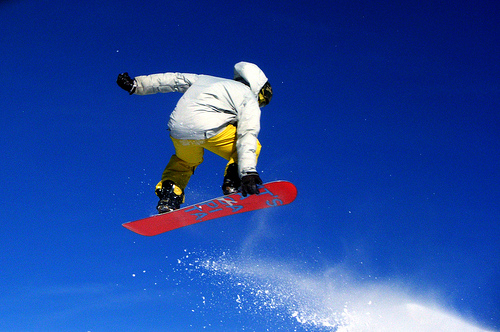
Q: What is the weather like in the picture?
A: It is clear.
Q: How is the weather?
A: It is clear.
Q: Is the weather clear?
A: Yes, it is clear.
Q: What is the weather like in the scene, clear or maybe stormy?
A: It is clear.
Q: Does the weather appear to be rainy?
A: No, it is clear.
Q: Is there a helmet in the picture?
A: No, there are no helmets.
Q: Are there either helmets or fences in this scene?
A: No, there are no helmets or fences.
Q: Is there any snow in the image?
A: Yes, there is snow.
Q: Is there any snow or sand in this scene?
A: Yes, there is snow.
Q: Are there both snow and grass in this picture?
A: No, there is snow but no grass.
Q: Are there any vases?
A: No, there are no vases.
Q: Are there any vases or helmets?
A: No, there are no vases or helmets.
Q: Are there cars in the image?
A: No, there are no cars.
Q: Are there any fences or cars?
A: No, there are no cars or fences.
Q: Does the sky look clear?
A: Yes, the sky is clear.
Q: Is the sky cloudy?
A: No, the sky is clear.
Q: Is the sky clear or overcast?
A: The sky is clear.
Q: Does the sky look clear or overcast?
A: The sky is clear.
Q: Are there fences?
A: No, there are no fences.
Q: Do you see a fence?
A: No, there are no fences.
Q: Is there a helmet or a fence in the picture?
A: No, there are no fences or helmets.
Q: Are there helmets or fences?
A: No, there are no fences or helmets.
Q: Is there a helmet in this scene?
A: No, there are no helmets.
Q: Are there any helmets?
A: No, there are no helmets.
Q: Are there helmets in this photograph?
A: No, there are no helmets.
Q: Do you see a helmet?
A: No, there are no helmets.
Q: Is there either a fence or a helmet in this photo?
A: No, there are no helmets or fences.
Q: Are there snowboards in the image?
A: Yes, there is a snowboard.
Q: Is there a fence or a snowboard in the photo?
A: Yes, there is a snowboard.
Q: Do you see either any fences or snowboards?
A: Yes, there is a snowboard.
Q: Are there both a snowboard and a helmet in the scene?
A: No, there is a snowboard but no helmets.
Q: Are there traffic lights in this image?
A: No, there are no traffic lights.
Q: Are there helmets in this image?
A: No, there are no helmets.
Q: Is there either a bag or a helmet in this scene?
A: No, there are no helmets or bags.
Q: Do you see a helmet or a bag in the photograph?
A: No, there are no helmets or bags.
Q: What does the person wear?
A: The person wears pants.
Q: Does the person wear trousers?
A: Yes, the person wears trousers.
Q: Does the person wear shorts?
A: No, the person wears trousers.